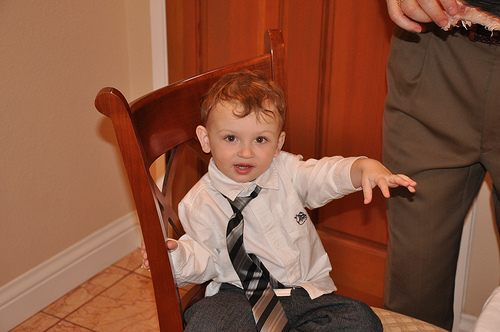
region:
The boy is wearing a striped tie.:
[197, 189, 288, 324]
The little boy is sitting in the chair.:
[108, 80, 374, 302]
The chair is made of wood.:
[68, 98, 193, 241]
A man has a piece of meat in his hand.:
[398, 0, 496, 42]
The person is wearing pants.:
[385, 50, 491, 263]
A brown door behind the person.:
[194, 24, 389, 134]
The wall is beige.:
[14, 23, 123, 202]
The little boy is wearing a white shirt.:
[185, 180, 340, 288]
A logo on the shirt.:
[288, 202, 311, 232]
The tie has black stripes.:
[233, 236, 280, 327]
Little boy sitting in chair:
[87, 53, 377, 295]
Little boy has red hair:
[210, 73, 314, 173]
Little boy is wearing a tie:
[219, 189, 286, 329]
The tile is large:
[71, 276, 102, 321]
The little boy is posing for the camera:
[167, 89, 364, 280]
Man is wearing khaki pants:
[381, 50, 495, 272]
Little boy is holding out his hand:
[295, 140, 450, 243]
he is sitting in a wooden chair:
[84, 72, 228, 271]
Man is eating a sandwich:
[426, 5, 494, 25]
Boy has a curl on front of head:
[191, 70, 286, 117]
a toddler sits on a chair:
[90, 23, 428, 330]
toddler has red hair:
[175, 55, 319, 226]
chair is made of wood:
[80, 15, 425, 330]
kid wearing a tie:
[165, 62, 413, 330]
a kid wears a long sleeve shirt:
[124, 63, 421, 330]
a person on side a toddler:
[374, 5, 498, 316]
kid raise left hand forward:
[141, 66, 426, 297]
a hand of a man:
[377, 0, 477, 41]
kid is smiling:
[178, 62, 303, 217]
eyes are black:
[214, 126, 278, 147]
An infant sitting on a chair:
[141, 69, 420, 329]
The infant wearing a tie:
[221, 193, 288, 330]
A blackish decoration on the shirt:
[293, 208, 308, 225]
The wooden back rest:
[122, 106, 194, 135]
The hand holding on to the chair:
[139, 236, 175, 269]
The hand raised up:
[353, 156, 419, 208]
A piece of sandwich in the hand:
[446, 1, 499, 35]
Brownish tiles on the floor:
[77, 292, 154, 330]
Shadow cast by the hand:
[394, 189, 407, 195]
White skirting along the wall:
[15, 276, 80, 285]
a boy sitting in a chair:
[79, 18, 439, 328]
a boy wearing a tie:
[171, 75, 302, 325]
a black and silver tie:
[211, 187, 281, 326]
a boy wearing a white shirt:
[173, 59, 373, 314]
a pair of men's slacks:
[382, 10, 498, 330]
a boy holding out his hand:
[184, 69, 421, 217]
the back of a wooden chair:
[94, 63, 221, 328]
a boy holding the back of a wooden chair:
[93, 65, 289, 284]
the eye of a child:
[220, 129, 242, 148]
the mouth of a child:
[231, 160, 256, 176]